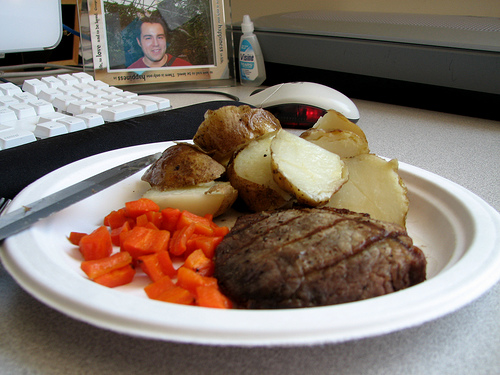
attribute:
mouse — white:
[230, 78, 366, 131]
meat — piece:
[209, 199, 429, 314]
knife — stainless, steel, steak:
[0, 149, 160, 239]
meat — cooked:
[218, 197, 425, 306]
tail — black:
[134, 79, 242, 104]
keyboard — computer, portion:
[2, 66, 165, 160]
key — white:
[73, 108, 106, 128]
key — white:
[59, 116, 86, 134]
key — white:
[35, 118, 70, 141]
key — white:
[42, 106, 69, 128]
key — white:
[102, 104, 148, 124]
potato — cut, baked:
[139, 103, 410, 228]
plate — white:
[37, 130, 494, 362]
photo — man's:
[90, 20, 182, 67]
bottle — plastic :
[236, 13, 265, 86]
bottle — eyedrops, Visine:
[237, 12, 267, 89]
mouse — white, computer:
[240, 75, 365, 132]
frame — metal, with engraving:
[70, 4, 235, 94]